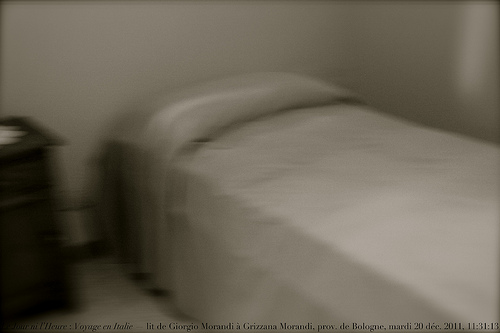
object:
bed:
[103, 68, 498, 333]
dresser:
[0, 115, 75, 333]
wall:
[0, 0, 349, 255]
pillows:
[100, 68, 351, 161]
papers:
[0, 118, 34, 148]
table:
[0, 115, 84, 333]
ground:
[0, 250, 205, 333]